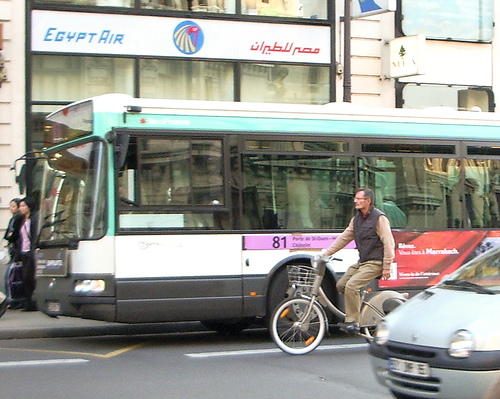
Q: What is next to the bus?
A: A man on a bicycle.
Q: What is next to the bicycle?
A: A bus.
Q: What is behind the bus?
A: A building.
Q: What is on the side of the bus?
A: A red sign.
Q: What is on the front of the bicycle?
A: A basket.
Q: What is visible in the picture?
A: A large bus.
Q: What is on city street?
A: A bus.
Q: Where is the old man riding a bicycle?
A: Down the road next to a large bus.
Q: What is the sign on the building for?
A: Egypt Air.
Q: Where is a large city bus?
A: On the side of the road.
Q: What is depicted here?
A: The front of a white car on the road.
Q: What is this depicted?
A: A bicycle.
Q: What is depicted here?
A: A bus.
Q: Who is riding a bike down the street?
A: A man.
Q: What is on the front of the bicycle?
A: A basket.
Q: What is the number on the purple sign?
A: 81.